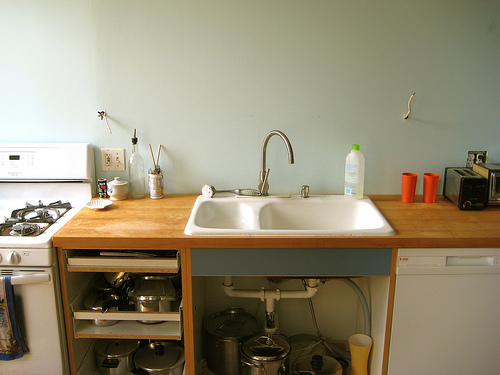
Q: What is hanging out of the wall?
A: Wires.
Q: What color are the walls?
A: Powder blue.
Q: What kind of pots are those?
A: Stainless steel.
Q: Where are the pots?
A: Under the sink.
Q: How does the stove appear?
A: Dirty.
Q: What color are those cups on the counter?
A: Orange.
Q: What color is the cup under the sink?
A: Yellow.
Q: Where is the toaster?
A: On the counter.